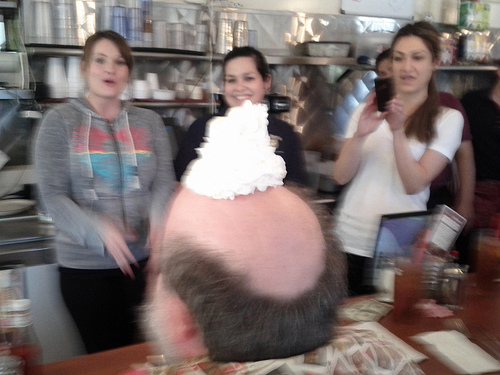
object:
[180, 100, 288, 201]
whipped cream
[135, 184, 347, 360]
head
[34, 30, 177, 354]
girl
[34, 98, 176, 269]
hoodie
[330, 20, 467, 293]
woman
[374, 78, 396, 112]
phone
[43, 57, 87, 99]
cups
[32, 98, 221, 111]
shelf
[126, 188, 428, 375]
man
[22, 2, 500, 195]
shelves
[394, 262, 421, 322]
drink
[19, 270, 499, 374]
table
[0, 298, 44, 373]
bottle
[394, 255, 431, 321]
glass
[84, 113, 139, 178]
strings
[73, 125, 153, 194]
heart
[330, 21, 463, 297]
girl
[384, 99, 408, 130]
hand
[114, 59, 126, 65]
left eye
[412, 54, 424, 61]
left eye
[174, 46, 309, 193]
girl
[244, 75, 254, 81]
left eye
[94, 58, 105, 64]
right eye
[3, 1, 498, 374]
diner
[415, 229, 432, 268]
straw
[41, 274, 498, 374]
counter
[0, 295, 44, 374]
condiments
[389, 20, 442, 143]
hair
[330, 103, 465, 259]
shirt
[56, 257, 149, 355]
pants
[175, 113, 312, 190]
shirt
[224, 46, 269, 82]
hair